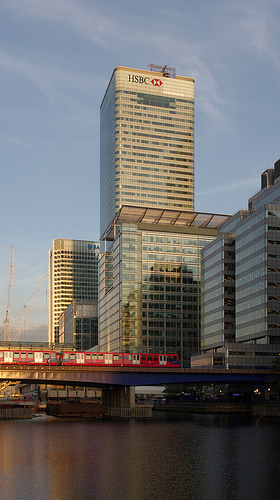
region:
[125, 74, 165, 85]
writting on a building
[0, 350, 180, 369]
a train on a bridge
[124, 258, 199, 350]
a reflection in windows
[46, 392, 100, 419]
a bridge under the bridge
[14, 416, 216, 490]
a reflection in the water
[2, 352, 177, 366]
a red and blue train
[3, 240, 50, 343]
a white and orange crane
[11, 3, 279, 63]
a clear blue sky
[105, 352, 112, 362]
a white door on a train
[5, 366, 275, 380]
a blue rail road bridge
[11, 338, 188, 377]
red train on bridge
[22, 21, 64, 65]
white clouds in blue sky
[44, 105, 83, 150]
white clouds in blue sky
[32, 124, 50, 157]
white clouds in blue sky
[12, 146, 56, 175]
white clouds in blue sky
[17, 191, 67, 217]
white clouds in blue sky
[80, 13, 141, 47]
white clouds in blue sky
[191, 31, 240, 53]
white clouds in blue sky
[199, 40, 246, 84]
white clouds in blue sky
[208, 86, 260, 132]
white clouds in blue sky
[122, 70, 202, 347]
tall building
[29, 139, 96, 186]
white clouds in blue sky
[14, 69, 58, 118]
white clouds in blue sky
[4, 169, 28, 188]
white clouds in blue sky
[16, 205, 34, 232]
white clouds in blue sky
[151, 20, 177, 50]
white clouds in blue sky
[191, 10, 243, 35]
white clouds in blue sky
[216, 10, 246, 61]
white clouds in blue sky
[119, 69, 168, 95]
black and white sign on building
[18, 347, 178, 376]
red train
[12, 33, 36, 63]
white clouds in blue sky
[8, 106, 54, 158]
white clouds in blue sky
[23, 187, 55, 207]
white clouds in blue sky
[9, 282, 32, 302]
white clouds in blue sky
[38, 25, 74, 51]
white clouds in blue sky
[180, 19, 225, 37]
white clouds in blue sky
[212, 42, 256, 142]
white clouds in blue sky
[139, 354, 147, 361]
this is a window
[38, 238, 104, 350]
this is a building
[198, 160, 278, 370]
this is a building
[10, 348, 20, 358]
this is a window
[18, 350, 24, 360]
this is a window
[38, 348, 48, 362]
this is a window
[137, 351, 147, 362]
this is a window